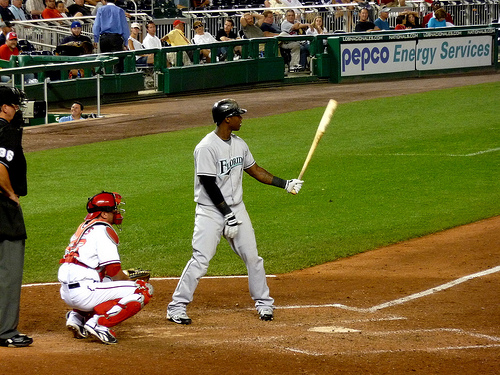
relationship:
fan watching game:
[140, 19, 165, 65] [0, 27, 497, 367]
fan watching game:
[258, 10, 303, 70] [0, 27, 497, 367]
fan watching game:
[256, 7, 283, 56] [0, 27, 497, 367]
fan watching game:
[119, 16, 149, 58] [0, 27, 497, 367]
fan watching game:
[423, 5, 463, 36] [0, 27, 497, 367]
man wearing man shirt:
[92, 3, 132, 74] [92, 1, 130, 51]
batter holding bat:
[164, 94, 303, 327] [296, 99, 340, 185]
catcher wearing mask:
[58, 190, 153, 345] [113, 192, 125, 232]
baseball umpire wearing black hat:
[1, 87, 33, 354] [2, 85, 24, 104]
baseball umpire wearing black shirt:
[1, 87, 33, 354] [1, 127, 29, 194]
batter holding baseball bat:
[164, 94, 303, 327] [286, 93, 342, 196]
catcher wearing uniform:
[54, 188, 157, 345] [54, 218, 152, 335]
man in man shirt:
[88, 2, 137, 72] [92, 1, 130, 51]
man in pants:
[88, 2, 137, 72] [99, 34, 121, 71]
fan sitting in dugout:
[142, 20, 166, 65] [17, 96, 135, 138]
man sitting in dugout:
[212, 14, 244, 66] [17, 96, 135, 138]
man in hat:
[0, 29, 24, 64] [6, 31, 20, 40]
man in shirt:
[0, 29, 24, 64] [0, 42, 25, 57]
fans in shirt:
[160, 19, 220, 63] [165, 27, 191, 47]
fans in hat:
[160, 19, 220, 63] [172, 19, 185, 24]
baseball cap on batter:
[212, 97, 246, 123] [164, 94, 303, 328]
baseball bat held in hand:
[280, 91, 352, 213] [270, 164, 310, 208]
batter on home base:
[164, 94, 303, 328] [301, 316, 373, 341]